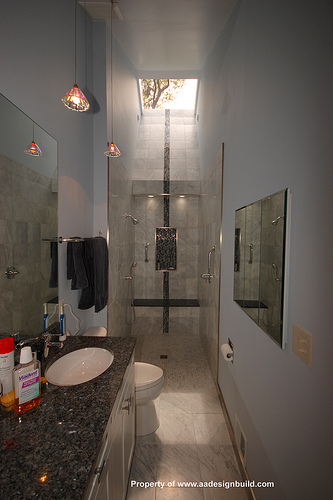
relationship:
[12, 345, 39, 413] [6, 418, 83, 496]
mouthwash on counter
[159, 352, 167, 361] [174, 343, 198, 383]
drain on ground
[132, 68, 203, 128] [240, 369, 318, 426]
panel on wall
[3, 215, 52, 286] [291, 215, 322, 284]
mirror hanging on wall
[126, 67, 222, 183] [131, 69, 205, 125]
shine from sky light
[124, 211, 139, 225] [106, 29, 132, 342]
shower head attached to wall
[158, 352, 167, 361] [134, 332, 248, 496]
drain in middle of floor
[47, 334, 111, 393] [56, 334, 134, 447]
sink on counter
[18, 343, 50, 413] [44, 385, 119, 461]
bottle on counter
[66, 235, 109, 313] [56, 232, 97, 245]
towel on rack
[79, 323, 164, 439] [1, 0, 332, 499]
toilet in bathroom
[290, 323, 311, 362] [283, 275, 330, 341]
light switches on wall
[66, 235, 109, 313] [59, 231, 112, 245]
towel hanging on rack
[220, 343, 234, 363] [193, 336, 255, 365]
paper on roll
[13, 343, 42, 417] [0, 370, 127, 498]
bottle on counter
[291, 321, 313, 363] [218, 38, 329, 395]
light switches on wall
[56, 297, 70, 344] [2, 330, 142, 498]
toothbrush on counter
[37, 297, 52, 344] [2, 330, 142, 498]
toothbrush on counter